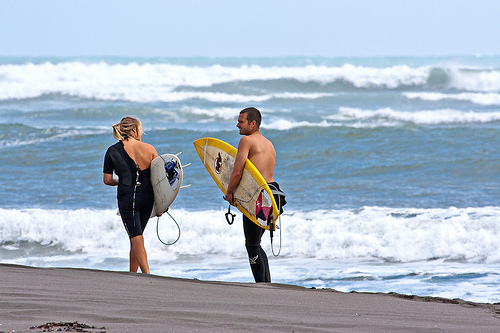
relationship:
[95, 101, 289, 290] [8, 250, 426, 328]
man/woman by sea shore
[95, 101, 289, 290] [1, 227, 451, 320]
man/woman by sea shore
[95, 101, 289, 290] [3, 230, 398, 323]
man/woman by sea shore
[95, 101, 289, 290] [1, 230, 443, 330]
man/woman by sea shore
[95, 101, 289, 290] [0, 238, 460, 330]
man/woman by sea shore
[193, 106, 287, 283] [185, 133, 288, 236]
man holding surfboard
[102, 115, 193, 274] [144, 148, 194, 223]
woman holding surfboard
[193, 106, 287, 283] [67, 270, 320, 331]
man on sea shore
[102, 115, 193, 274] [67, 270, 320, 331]
woman on sea shore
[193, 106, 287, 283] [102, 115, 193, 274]
man next to woman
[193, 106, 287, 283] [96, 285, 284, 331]
man next to sea shore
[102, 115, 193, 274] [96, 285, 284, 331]
woman next to sea shore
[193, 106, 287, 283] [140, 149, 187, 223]
man holding surfboard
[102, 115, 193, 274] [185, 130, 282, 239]
woman holding surfboard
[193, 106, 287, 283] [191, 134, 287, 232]
man holding surfboard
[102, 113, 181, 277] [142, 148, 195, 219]
woman holding surfboard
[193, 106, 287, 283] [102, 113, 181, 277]
man next to woman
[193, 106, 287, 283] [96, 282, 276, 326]
man on sea shore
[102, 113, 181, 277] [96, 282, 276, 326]
woman on sea shore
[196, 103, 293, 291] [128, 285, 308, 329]
man on sea shore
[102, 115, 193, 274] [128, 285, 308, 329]
woman on sea shore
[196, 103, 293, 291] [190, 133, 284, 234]
man holding surf boards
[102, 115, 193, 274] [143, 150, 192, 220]
woman holding surf boards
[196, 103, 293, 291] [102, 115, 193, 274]
man next to woman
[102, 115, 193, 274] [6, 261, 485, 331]
woman walking beach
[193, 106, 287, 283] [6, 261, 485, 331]
man walking beach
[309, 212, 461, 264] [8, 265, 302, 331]
wave washing on beach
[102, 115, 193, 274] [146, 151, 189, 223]
woman holding surfboard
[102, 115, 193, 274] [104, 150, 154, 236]
woman wearing wetsuit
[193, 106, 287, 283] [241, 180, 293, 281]
man wearing pants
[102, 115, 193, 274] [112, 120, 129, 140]
woman has pony tail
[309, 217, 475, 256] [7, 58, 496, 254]
wave are in ocean